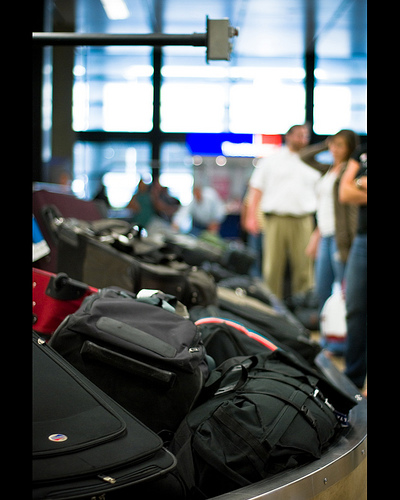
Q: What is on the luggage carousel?
A: Luggage.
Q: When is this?
A: Daytime.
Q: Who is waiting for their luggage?
A: Airline passengers.